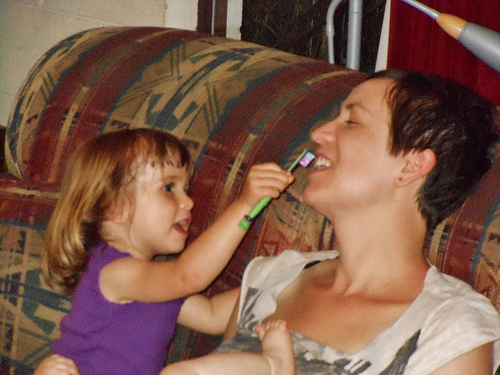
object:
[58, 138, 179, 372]
girl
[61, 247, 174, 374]
shirt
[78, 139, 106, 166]
hair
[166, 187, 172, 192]
eye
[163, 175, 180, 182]
eyebrow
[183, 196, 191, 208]
nose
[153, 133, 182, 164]
bangs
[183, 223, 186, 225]
teeth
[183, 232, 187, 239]
lip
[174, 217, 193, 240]
mouth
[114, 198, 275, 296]
arm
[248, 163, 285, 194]
hand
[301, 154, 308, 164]
toothbrush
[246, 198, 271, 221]
handle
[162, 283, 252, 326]
arm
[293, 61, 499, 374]
woman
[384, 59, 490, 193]
hair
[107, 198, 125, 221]
ear